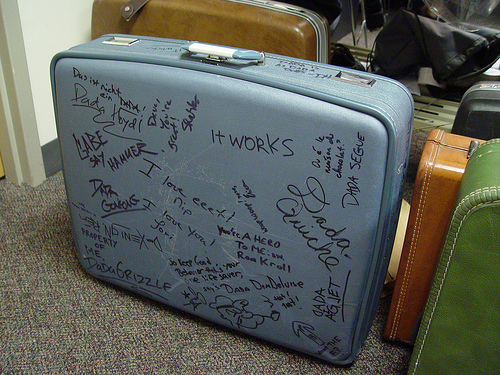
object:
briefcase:
[451, 79, 500, 142]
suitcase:
[408, 135, 498, 374]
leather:
[458, 214, 496, 288]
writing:
[104, 142, 165, 174]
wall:
[19, 0, 93, 145]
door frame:
[0, 0, 49, 190]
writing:
[338, 129, 368, 212]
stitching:
[386, 128, 446, 347]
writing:
[275, 196, 341, 273]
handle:
[178, 35, 267, 69]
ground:
[5, 175, 420, 370]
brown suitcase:
[381, 127, 489, 346]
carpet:
[0, 63, 432, 374]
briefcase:
[48, 26, 417, 368]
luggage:
[87, 0, 332, 67]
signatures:
[199, 123, 305, 159]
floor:
[0, 76, 467, 372]